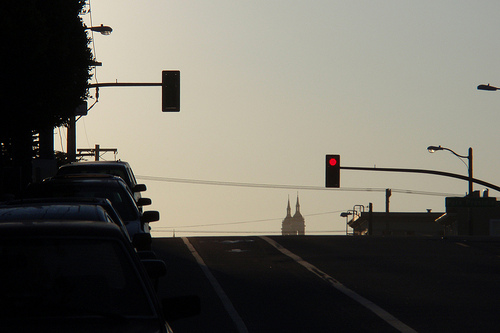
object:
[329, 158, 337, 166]
light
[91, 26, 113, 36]
light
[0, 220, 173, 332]
car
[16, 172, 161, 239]
car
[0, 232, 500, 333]
street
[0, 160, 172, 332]
cars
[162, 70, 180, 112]
street light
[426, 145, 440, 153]
street light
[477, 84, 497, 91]
street light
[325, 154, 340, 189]
street light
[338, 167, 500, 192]
pole